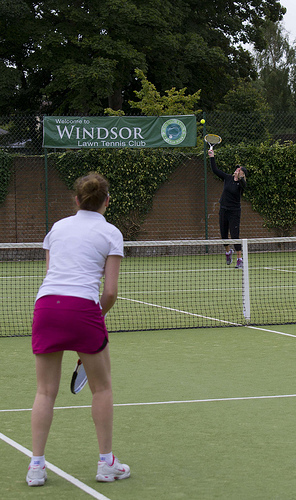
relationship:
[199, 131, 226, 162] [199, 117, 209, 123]
racket hits ball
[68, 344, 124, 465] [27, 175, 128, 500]
leg of woman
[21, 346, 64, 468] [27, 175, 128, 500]
leg of woman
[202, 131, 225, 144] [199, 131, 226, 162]
head of racket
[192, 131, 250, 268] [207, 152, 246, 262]
woman wears black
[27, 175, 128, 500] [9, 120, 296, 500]
woman plays tennis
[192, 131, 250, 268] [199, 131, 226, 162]
woman has racket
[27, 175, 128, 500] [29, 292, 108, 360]
woman wears shorts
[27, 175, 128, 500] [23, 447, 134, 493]
woman wears shoes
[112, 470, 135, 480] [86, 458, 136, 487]
logo on shoe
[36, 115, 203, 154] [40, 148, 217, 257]
banner on poles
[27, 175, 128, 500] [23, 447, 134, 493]
girl wears shoes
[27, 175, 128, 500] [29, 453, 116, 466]
girl wears socks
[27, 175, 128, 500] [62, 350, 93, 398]
woman holds racket